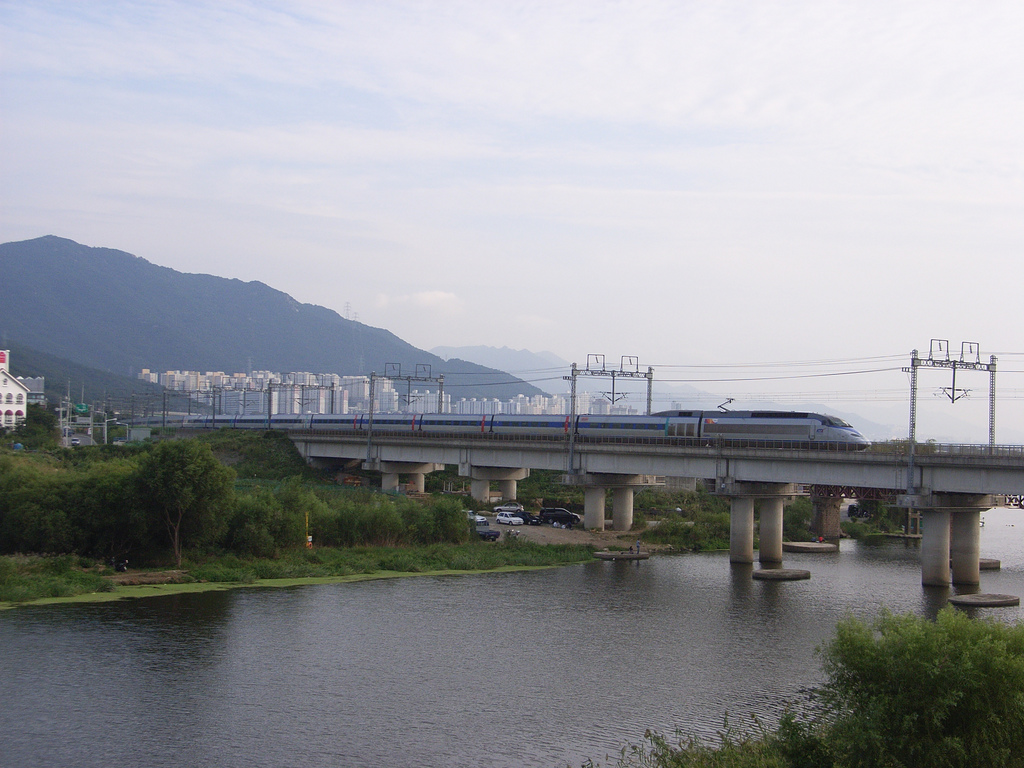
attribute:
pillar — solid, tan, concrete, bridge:
[377, 452, 417, 513]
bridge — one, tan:
[165, 413, 1019, 647]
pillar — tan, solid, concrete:
[396, 437, 444, 509]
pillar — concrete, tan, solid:
[491, 459, 533, 529]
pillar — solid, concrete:
[574, 476, 613, 548]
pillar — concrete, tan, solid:
[595, 474, 662, 557]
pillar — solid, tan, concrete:
[712, 487, 786, 565]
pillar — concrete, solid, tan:
[913, 495, 959, 606]